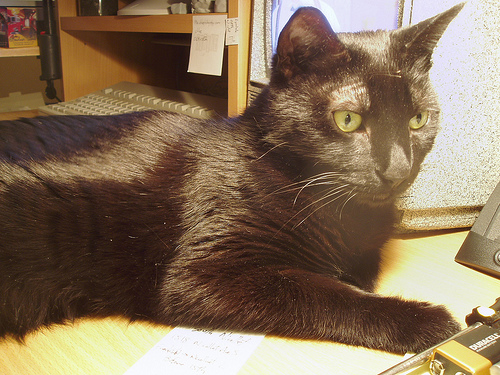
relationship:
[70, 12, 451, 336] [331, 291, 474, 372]
cat has paw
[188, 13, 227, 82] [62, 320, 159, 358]
paper on desk